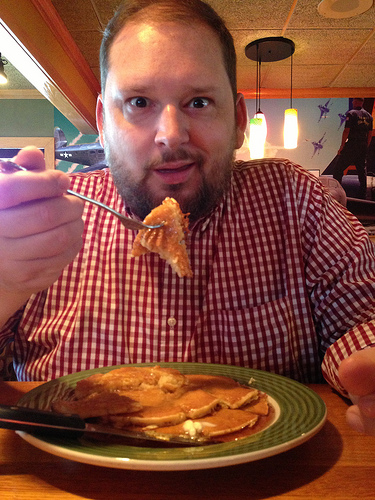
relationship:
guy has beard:
[2, 3, 375, 428] [104, 146, 236, 224]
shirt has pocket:
[0, 155, 374, 386] [203, 293, 300, 364]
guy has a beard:
[2, 3, 375, 428] [104, 146, 236, 224]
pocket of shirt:
[203, 293, 300, 364] [0, 155, 374, 386]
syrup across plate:
[209, 417, 270, 446] [8, 356, 331, 476]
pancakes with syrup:
[73, 352, 267, 435] [209, 417, 270, 446]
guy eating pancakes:
[2, 3, 375, 428] [73, 352, 267, 435]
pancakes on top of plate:
[73, 352, 267, 435] [8, 356, 331, 476]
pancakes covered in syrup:
[73, 352, 267, 435] [209, 417, 270, 446]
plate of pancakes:
[8, 356, 331, 476] [73, 352, 267, 435]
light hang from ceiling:
[281, 103, 303, 153] [54, 2, 370, 99]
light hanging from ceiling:
[281, 103, 303, 153] [54, 2, 370, 99]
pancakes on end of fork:
[73, 352, 267, 435] [8, 158, 165, 236]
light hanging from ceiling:
[281, 103, 303, 153] [47, 0, 374, 87]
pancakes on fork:
[73, 352, 267, 435] [1, 157, 166, 242]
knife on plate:
[1, 400, 166, 445] [6, 362, 327, 469]